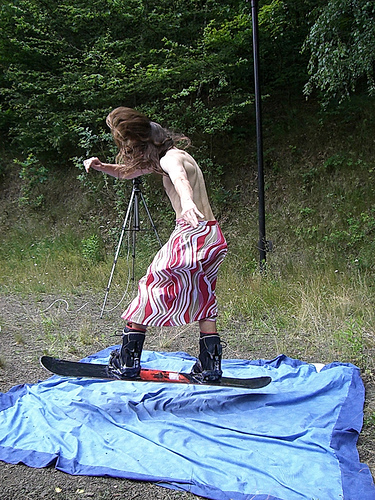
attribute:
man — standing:
[84, 123, 238, 382]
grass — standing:
[4, 154, 370, 358]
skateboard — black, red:
[38, 354, 272, 390]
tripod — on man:
[97, 177, 162, 252]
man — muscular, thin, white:
[84, 105, 227, 384]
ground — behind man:
[291, 130, 302, 152]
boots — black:
[106, 321, 241, 384]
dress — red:
[84, 214, 254, 358]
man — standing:
[82, 78, 263, 378]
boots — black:
[98, 328, 239, 392]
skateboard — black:
[52, 326, 274, 402]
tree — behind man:
[2, 10, 265, 176]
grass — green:
[249, 278, 357, 348]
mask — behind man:
[99, 103, 193, 184]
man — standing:
[72, 134, 230, 377]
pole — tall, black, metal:
[237, 86, 297, 250]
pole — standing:
[247, 0, 267, 279]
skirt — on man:
[118, 216, 233, 328]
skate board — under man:
[12, 309, 332, 452]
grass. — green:
[226, 239, 350, 323]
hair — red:
[97, 103, 194, 173]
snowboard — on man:
[37, 356, 272, 389]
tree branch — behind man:
[67, 118, 97, 152]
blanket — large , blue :
[0, 342, 373, 498]